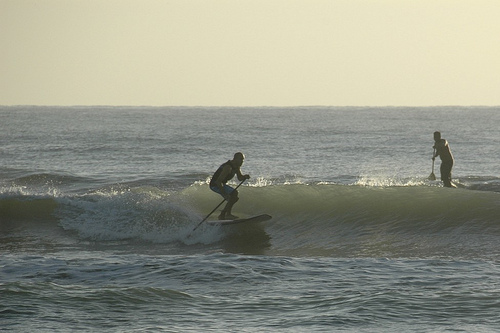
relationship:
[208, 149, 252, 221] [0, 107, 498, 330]
man on water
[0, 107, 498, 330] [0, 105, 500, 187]
water has gentle portion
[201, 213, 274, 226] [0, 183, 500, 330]
surf board in water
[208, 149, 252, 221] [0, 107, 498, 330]
man in water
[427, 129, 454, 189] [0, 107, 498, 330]
man in water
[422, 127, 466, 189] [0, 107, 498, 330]
man in water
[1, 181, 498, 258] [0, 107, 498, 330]
wave in water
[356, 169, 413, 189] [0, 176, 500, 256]
white curl on waves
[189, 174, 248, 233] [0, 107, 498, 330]
paddle in water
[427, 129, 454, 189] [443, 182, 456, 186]
man on surfboard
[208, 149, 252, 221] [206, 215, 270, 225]
man on surfboard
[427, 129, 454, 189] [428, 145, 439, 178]
man holding paddle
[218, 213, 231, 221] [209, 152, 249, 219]
foot on surfboard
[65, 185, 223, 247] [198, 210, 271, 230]
trail left by surfboard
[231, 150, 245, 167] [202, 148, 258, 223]
head of man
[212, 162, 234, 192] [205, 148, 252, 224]
arm of person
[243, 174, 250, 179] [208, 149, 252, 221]
hand of man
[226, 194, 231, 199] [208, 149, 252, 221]
hand of man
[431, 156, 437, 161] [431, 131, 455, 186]
hand of person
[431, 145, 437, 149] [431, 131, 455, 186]
hand of person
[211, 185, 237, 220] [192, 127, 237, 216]
leg belonging to person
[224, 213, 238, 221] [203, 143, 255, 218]
foot belonging to person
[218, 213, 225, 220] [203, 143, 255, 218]
foot belonging to person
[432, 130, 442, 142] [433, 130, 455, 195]
head belonging to person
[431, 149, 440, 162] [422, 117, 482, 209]
arm belonging to person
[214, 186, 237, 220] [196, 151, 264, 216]
leg belonging to person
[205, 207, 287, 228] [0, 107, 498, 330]
surf board floating on water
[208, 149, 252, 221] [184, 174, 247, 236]
man holding paddle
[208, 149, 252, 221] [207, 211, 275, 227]
man standing on board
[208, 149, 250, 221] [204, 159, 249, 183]
man wearing jacket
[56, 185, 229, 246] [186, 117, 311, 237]
trail flowing near man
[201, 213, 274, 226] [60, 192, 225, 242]
surf board creating wake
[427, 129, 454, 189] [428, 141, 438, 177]
man holding paddle